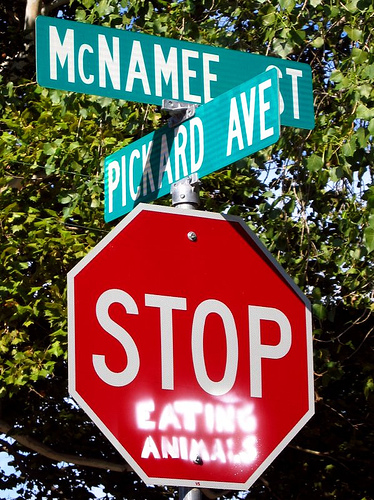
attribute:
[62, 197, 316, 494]
sign — stop, red, white, vandalized, octagon, large, aluminum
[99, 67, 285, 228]
sign — green, white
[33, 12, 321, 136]
sign — green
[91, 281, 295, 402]
letters — white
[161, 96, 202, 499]
pole — silver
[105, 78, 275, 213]
lettering — white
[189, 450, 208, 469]
screw — metal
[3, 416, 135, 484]
limb — brown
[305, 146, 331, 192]
leaf — green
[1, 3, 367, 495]
sky — clear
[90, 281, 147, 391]
letter — white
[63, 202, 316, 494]
outline — white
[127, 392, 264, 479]
hand writing — white